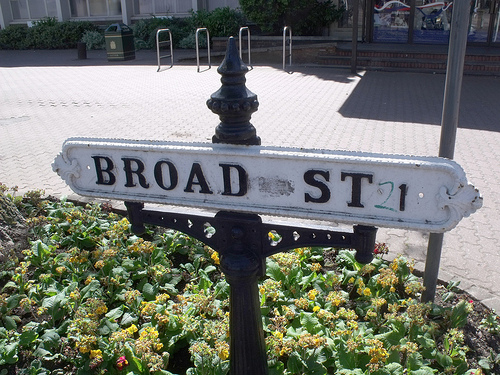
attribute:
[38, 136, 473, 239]
board — black, white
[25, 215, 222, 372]
flowers — yellow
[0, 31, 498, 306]
drive — brick paved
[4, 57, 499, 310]
pathway — grey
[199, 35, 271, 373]
pole — black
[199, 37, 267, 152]
top — sharp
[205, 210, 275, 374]
pole — black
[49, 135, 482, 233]
post — white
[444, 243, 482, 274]
bricks — concrete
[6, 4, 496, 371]
picture — day time